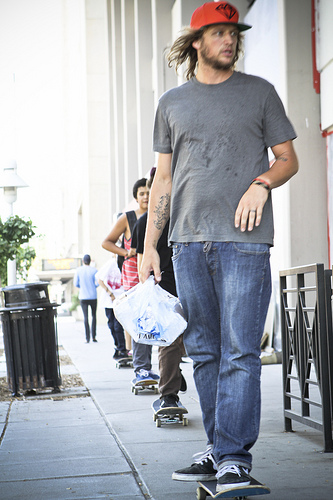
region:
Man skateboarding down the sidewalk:
[175, 9, 312, 499]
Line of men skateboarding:
[92, 149, 288, 498]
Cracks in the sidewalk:
[23, 415, 127, 497]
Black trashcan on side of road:
[1, 278, 62, 397]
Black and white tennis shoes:
[175, 445, 260, 492]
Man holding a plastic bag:
[109, 268, 194, 336]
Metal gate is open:
[274, 260, 331, 436]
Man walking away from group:
[56, 243, 106, 347]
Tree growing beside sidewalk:
[3, 211, 49, 278]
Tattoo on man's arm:
[157, 188, 170, 247]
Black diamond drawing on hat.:
[212, 4, 237, 20]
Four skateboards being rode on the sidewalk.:
[112, 347, 283, 494]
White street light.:
[2, 160, 21, 285]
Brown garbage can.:
[1, 278, 68, 402]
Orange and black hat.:
[187, 2, 255, 29]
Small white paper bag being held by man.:
[109, 272, 184, 350]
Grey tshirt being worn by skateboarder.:
[149, 76, 295, 248]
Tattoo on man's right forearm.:
[150, 186, 174, 239]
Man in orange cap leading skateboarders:
[96, 0, 293, 498]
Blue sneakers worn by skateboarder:
[133, 368, 156, 386]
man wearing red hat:
[184, 3, 265, 29]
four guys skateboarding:
[101, 341, 272, 498]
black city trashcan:
[1, 281, 71, 398]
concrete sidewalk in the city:
[9, 400, 151, 496]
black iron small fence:
[275, 267, 322, 444]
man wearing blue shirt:
[69, 251, 101, 301]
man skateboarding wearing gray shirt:
[107, 4, 299, 496]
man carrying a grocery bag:
[115, 0, 287, 498]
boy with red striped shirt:
[94, 208, 149, 290]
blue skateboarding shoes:
[122, 362, 161, 395]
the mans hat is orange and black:
[184, 2, 255, 38]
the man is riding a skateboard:
[120, 1, 314, 499]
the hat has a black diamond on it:
[209, 2, 244, 24]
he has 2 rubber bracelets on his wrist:
[253, 178, 273, 194]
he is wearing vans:
[169, 444, 271, 493]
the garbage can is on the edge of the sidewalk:
[2, 280, 76, 395]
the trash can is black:
[1, 281, 65, 402]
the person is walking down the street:
[70, 247, 102, 350]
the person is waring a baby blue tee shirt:
[74, 264, 100, 300]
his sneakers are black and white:
[167, 454, 258, 495]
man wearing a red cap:
[111, 4, 311, 498]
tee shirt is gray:
[135, 69, 301, 247]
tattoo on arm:
[146, 180, 177, 238]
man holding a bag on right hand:
[98, 1, 309, 495]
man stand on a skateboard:
[97, 0, 306, 498]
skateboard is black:
[179, 451, 276, 498]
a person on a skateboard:
[134, 166, 197, 436]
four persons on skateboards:
[92, 0, 300, 498]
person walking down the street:
[71, 251, 105, 347]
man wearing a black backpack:
[96, 178, 149, 289]